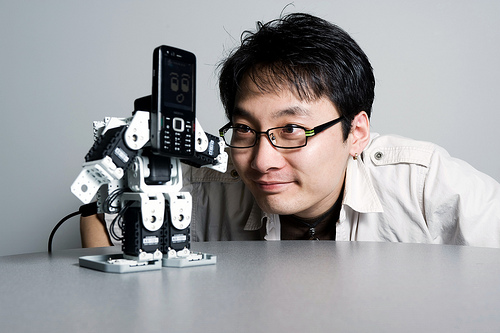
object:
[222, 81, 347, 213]
face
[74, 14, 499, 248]
man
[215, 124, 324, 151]
glasses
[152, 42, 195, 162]
mobile phone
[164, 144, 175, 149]
key pad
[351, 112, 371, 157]
ear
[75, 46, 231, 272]
robot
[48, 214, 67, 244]
wires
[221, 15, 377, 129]
hair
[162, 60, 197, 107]
display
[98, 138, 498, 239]
jacket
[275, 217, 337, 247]
shirt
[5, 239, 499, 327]
table